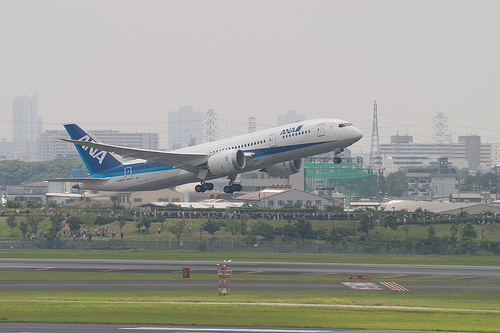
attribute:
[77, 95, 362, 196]
plane — white & blue, here, white, flying, blue, large, long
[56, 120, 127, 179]
tail — white, blue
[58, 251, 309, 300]
runway — here, black, close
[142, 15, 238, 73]
sky — white, above, stormy, dark, overcast, black, grey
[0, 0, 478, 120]
sky — overcast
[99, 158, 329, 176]
stripe — light blue, dark blue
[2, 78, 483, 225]
buildings — large, in distance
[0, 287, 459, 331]
grass — green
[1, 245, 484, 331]
grass — green